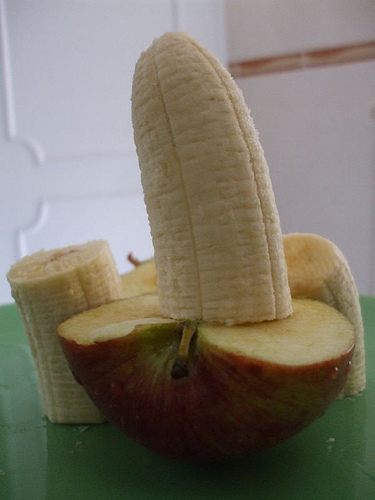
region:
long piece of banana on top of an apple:
[128, 25, 293, 323]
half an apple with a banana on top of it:
[51, 290, 352, 462]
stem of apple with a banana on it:
[165, 316, 196, 378]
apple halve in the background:
[116, 248, 153, 294]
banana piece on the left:
[2, 233, 122, 422]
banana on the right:
[280, 230, 363, 395]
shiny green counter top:
[0, 292, 370, 498]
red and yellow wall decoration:
[225, 36, 368, 70]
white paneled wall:
[0, 0, 225, 301]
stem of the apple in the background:
[126, 251, 142, 264]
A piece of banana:
[112, 32, 305, 329]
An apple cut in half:
[63, 295, 350, 439]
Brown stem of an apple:
[153, 324, 219, 393]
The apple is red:
[59, 299, 363, 440]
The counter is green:
[22, 324, 362, 479]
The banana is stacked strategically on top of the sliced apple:
[56, 26, 352, 421]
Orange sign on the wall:
[227, 27, 371, 89]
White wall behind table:
[5, 62, 137, 232]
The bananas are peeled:
[15, 39, 367, 407]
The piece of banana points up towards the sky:
[113, 24, 308, 325]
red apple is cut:
[55, 290, 355, 463]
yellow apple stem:
[170, 323, 195, 378]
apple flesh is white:
[57, 292, 182, 345]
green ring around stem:
[137, 320, 202, 376]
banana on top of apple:
[131, 33, 290, 321]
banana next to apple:
[7, 241, 123, 426]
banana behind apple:
[284, 232, 364, 395]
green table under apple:
[1, 294, 373, 497]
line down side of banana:
[149, 48, 204, 322]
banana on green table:
[7, 241, 127, 423]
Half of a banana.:
[120, 22, 279, 329]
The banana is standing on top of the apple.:
[45, 30, 374, 469]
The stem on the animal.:
[166, 318, 197, 380]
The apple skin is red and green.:
[47, 330, 362, 469]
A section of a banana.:
[6, 241, 130, 425]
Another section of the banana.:
[277, 233, 372, 399]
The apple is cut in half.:
[56, 285, 360, 465]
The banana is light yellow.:
[123, 23, 300, 323]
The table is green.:
[8, 436, 110, 485]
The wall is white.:
[27, 61, 111, 127]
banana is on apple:
[100, 46, 303, 335]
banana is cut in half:
[85, 23, 307, 378]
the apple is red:
[56, 266, 362, 459]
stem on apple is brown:
[159, 309, 223, 381]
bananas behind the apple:
[7, 198, 345, 446]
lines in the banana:
[141, 46, 295, 324]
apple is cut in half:
[90, 272, 363, 440]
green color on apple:
[241, 364, 357, 444]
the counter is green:
[0, 294, 358, 493]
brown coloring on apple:
[251, 311, 343, 362]